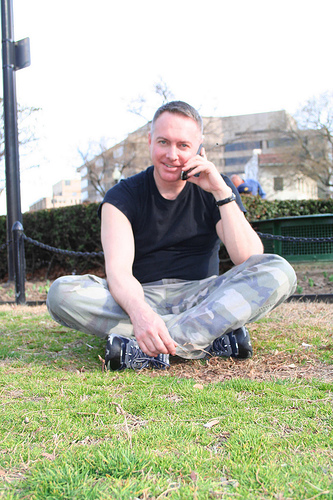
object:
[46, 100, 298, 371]
man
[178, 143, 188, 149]
eye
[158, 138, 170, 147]
eye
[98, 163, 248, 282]
black shirt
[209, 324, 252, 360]
sneaker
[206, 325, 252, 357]
foot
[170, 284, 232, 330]
camoflage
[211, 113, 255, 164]
ground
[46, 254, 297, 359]
army pants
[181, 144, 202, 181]
cell phone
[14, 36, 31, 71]
sign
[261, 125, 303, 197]
ground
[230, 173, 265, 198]
man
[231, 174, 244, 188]
head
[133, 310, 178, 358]
hand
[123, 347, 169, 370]
shoelaces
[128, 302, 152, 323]
wrist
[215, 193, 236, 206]
watch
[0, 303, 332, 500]
grass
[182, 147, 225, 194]
hand